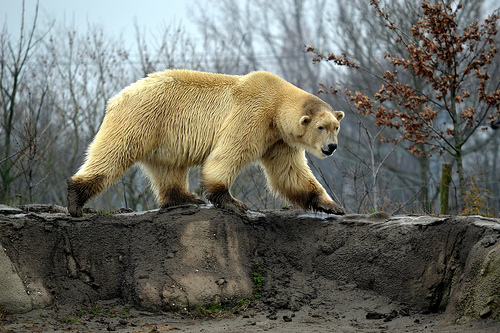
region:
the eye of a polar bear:
[315, 120, 327, 134]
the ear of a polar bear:
[298, 109, 313, 126]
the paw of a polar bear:
[203, 175, 250, 213]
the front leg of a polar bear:
[198, 110, 253, 215]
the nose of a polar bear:
[322, 138, 342, 151]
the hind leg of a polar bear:
[60, 114, 130, 218]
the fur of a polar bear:
[168, 77, 228, 119]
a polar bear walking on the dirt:
[69, 65, 374, 237]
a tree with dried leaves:
[383, 8, 484, 158]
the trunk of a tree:
[457, 163, 467, 199]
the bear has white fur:
[113, 85, 318, 144]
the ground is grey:
[257, 239, 416, 289]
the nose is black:
[324, 142, 344, 156]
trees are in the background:
[241, 26, 374, 40]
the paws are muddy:
[62, 187, 94, 224]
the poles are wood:
[426, 162, 459, 213]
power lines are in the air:
[59, 51, 229, 66]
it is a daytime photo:
[8, 7, 493, 327]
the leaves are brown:
[373, 76, 441, 148]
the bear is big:
[61, 75, 343, 213]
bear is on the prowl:
[59, 67, 379, 213]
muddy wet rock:
[2, 218, 497, 330]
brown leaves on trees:
[318, 14, 498, 132]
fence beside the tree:
[337, 162, 494, 215]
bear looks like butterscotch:
[50, 77, 343, 212]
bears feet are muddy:
[62, 169, 349, 214]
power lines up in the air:
[7, 45, 363, 72]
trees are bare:
[0, 1, 51, 206]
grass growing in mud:
[65, 264, 317, 327]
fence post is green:
[426, 161, 458, 221]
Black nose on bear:
[326, 142, 338, 150]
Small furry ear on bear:
[298, 112, 311, 126]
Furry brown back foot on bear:
[70, 175, 98, 215]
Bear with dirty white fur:
[67, 68, 350, 220]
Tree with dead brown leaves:
[338, 0, 498, 218]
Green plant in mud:
[193, 269, 272, 326]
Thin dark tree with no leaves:
[3, 1, 43, 199]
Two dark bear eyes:
[319, 121, 339, 133]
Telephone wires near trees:
[3, 51, 386, 66]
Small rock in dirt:
[214, 275, 226, 286]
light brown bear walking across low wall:
[52, 58, 349, 234]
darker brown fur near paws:
[57, 170, 372, 222]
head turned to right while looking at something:
[285, 81, 365, 166]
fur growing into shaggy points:
[90, 71, 276, 167]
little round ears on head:
[290, 101, 350, 126]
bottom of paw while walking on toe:
[40, 145, 106, 225]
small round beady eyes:
[310, 117, 340, 132]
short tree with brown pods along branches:
[345, 5, 490, 190]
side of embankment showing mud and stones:
[120, 201, 465, 316]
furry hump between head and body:
[230, 60, 293, 121]